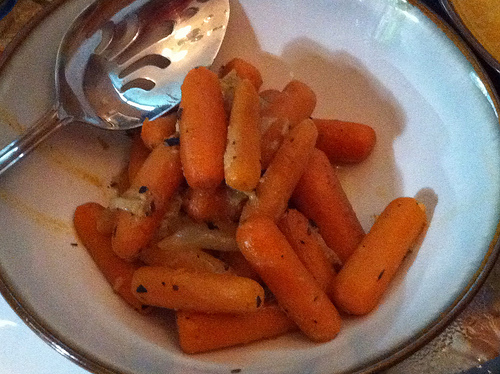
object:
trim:
[428, 26, 493, 93]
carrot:
[330, 195, 427, 317]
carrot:
[176, 301, 299, 356]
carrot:
[69, 199, 160, 316]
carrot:
[238, 117, 319, 225]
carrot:
[296, 146, 367, 261]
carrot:
[259, 78, 318, 175]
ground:
[0, 0, 500, 374]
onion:
[107, 187, 154, 217]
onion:
[157, 224, 239, 251]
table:
[0, 0, 500, 374]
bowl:
[0, 0, 500, 372]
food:
[68, 56, 435, 356]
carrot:
[111, 146, 183, 265]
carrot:
[230, 213, 343, 344]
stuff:
[160, 281, 166, 286]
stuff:
[256, 294, 263, 309]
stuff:
[313, 294, 319, 302]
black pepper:
[135, 282, 148, 293]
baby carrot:
[329, 193, 429, 318]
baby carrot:
[176, 62, 228, 195]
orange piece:
[276, 207, 347, 300]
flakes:
[170, 284, 182, 293]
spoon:
[0, 0, 234, 182]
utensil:
[436, 20, 489, 70]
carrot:
[310, 116, 379, 168]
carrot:
[222, 77, 262, 195]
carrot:
[130, 263, 267, 314]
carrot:
[181, 181, 223, 224]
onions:
[227, 190, 247, 207]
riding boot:
[138, 242, 232, 276]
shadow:
[206, 0, 439, 231]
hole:
[117, 52, 174, 81]